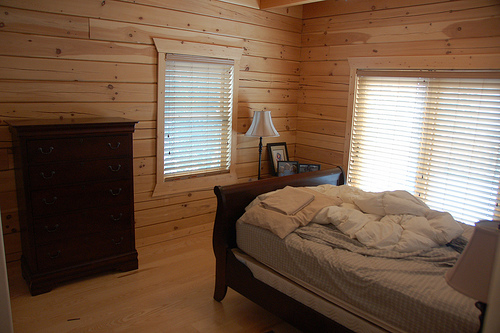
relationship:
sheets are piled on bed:
[243, 196, 479, 319] [206, 168, 492, 327]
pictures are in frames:
[280, 164, 291, 173] [266, 141, 321, 175]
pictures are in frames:
[273, 146, 285, 157] [266, 141, 321, 175]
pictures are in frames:
[302, 163, 317, 168] [266, 141, 321, 175]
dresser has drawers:
[5, 115, 140, 298] [29, 134, 130, 267]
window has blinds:
[150, 35, 243, 197] [167, 57, 228, 170]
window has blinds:
[346, 55, 499, 220] [358, 76, 494, 207]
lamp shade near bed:
[446, 219, 498, 309] [206, 168, 492, 327]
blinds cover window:
[358, 76, 494, 207] [346, 55, 499, 220]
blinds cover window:
[167, 57, 228, 170] [150, 35, 243, 197]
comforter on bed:
[340, 185, 459, 255] [206, 168, 492, 327]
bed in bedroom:
[206, 168, 492, 327] [4, 1, 498, 333]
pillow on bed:
[240, 185, 349, 239] [206, 168, 492, 327]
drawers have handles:
[29, 134, 130, 267] [35, 140, 66, 270]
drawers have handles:
[29, 134, 130, 267] [105, 137, 128, 251]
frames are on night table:
[266, 141, 321, 175] [254, 171, 306, 179]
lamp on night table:
[247, 108, 280, 181] [254, 171, 306, 179]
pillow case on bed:
[259, 185, 314, 214] [206, 168, 492, 327]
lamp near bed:
[247, 108, 280, 181] [206, 168, 492, 327]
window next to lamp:
[150, 35, 243, 197] [247, 108, 280, 181]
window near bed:
[346, 55, 499, 220] [206, 168, 492, 327]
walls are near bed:
[307, 5, 497, 64] [206, 168, 492, 327]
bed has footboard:
[206, 168, 492, 327] [210, 165, 357, 305]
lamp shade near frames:
[244, 109, 279, 138] [266, 141, 321, 175]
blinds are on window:
[167, 57, 228, 170] [150, 35, 243, 197]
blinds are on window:
[358, 76, 494, 207] [346, 55, 499, 220]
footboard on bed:
[210, 165, 357, 305] [206, 168, 492, 327]